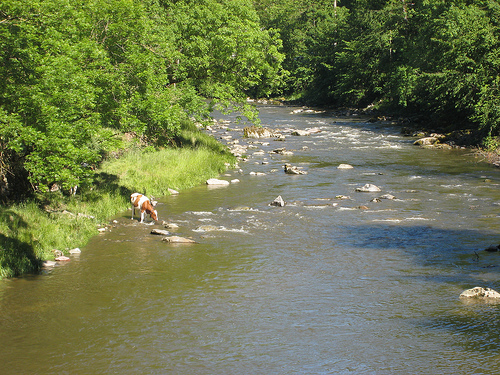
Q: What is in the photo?
A: A cow.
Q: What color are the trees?
A: Green.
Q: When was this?
A: Daytime.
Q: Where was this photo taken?
A: Near a stream.